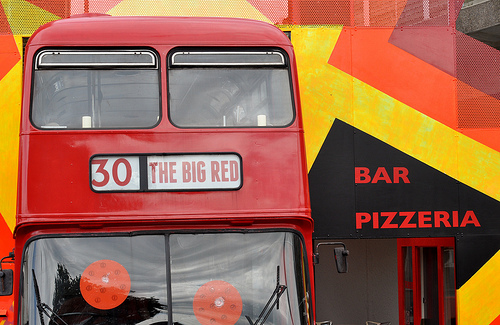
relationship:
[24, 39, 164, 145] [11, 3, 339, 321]
window on top of bus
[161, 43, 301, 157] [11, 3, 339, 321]
window on top of bus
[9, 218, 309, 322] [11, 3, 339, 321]
windshield on bottom of bus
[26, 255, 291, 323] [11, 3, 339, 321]
wipers on bottom of bus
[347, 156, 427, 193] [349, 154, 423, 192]
word in letters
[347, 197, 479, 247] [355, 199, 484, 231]
word in letters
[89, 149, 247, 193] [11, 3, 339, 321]
sign on bus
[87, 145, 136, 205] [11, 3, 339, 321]
numbers on bus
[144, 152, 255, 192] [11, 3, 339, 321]
letters on bus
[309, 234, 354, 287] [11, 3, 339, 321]
mirror on bus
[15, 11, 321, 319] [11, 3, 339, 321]
windows of bus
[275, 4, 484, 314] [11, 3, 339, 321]
building behind bus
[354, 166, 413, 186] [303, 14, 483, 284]
word on building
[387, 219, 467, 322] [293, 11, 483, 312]
door of building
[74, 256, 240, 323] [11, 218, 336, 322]
circles on window